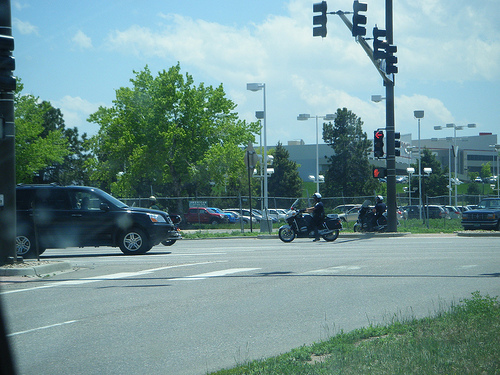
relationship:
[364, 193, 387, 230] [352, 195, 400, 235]
man riding motorcycle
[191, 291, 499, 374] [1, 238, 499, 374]
grass by road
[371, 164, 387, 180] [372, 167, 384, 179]
signal means signal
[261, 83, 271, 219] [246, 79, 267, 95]
pole has light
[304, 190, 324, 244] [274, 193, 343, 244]
man on motorcycle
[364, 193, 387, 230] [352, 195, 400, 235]
police officer on motorcycle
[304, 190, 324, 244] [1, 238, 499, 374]
police officer in road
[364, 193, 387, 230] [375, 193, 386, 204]
man wearing helmet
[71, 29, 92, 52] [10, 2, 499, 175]
cloud in sky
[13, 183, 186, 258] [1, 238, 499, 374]
car on road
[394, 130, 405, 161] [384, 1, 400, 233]
streetlight on pole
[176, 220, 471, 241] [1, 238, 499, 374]
grass beside road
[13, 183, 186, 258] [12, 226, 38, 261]
vehicle has tire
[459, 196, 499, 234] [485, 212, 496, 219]
truck has headlight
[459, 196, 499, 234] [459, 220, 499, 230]
truck has fender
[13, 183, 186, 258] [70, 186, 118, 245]
suv has door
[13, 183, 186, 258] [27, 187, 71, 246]
suv has door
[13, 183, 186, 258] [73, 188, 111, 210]
suv has window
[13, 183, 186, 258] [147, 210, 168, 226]
suv has headlight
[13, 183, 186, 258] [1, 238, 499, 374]
suv on road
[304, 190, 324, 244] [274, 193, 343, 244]
man aiding motorcycle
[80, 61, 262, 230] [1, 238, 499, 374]
tree near road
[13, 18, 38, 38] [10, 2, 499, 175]
cloud in sky